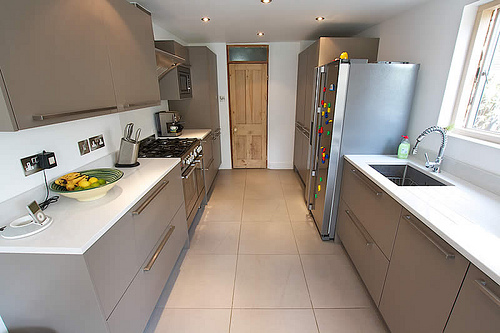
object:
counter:
[0, 156, 184, 253]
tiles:
[167, 253, 239, 309]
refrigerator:
[305, 57, 422, 243]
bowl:
[47, 166, 127, 202]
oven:
[136, 134, 199, 157]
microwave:
[159, 65, 194, 101]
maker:
[153, 110, 185, 138]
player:
[25, 199, 50, 226]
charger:
[36, 151, 58, 170]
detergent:
[397, 134, 412, 159]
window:
[435, 0, 500, 149]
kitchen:
[0, 26, 500, 307]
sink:
[364, 162, 456, 187]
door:
[227, 62, 271, 171]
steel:
[310, 60, 350, 240]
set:
[112, 122, 143, 170]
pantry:
[165, 45, 223, 200]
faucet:
[407, 124, 449, 172]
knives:
[123, 123, 131, 141]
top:
[123, 122, 142, 144]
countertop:
[155, 128, 213, 139]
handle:
[131, 179, 174, 217]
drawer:
[83, 159, 186, 322]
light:
[199, 15, 212, 23]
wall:
[350, 0, 500, 174]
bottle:
[396, 136, 412, 160]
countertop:
[338, 153, 500, 284]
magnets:
[327, 102, 332, 109]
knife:
[135, 127, 142, 144]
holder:
[116, 136, 142, 168]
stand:
[32, 216, 50, 226]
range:
[181, 145, 204, 168]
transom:
[226, 44, 269, 64]